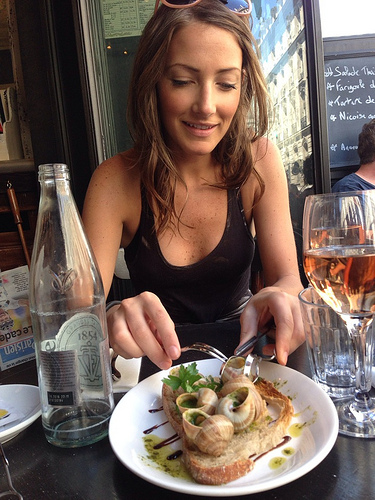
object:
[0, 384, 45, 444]
plate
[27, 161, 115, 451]
bottle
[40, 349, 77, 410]
label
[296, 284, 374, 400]
glass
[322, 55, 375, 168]
chalk board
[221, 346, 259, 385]
opener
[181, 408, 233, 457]
escargo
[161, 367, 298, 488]
bread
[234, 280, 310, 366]
hand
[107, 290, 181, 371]
hand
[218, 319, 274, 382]
silver utensil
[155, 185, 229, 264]
freckled body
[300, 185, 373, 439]
glass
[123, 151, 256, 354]
shirt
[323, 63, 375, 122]
menu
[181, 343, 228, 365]
fork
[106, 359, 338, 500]
plate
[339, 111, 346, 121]
writing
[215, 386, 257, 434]
escargot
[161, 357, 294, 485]
toast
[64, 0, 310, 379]
woman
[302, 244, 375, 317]
liquid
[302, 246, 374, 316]
beverage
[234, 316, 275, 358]
handle